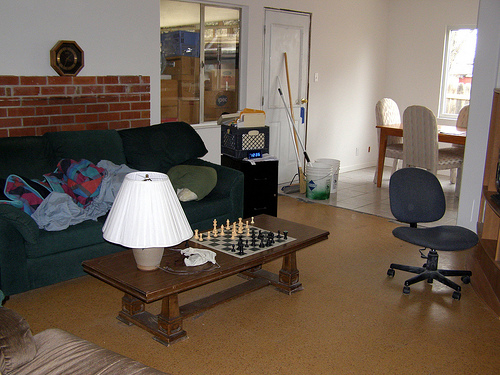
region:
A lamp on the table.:
[100, 149, 190, 272]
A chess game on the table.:
[201, 203, 297, 277]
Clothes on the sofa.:
[23, 122, 140, 212]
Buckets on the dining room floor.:
[286, 140, 353, 198]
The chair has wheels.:
[385, 253, 486, 294]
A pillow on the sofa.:
[152, 168, 230, 213]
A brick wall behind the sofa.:
[13, 63, 160, 131]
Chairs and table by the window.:
[355, 88, 467, 168]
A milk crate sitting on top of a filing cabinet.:
[220, 116, 275, 156]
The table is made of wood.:
[95, 252, 220, 337]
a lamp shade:
[97, 178, 190, 245]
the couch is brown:
[24, 338, 86, 373]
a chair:
[402, 115, 434, 163]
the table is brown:
[97, 255, 135, 289]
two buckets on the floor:
[306, 157, 339, 197]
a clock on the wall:
[47, 43, 91, 77]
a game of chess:
[202, 227, 272, 252]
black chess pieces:
[234, 228, 287, 251]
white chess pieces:
[197, 220, 259, 239]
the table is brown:
[387, 121, 399, 134]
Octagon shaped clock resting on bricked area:
[44, 31, 89, 80]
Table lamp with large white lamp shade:
[98, 167, 198, 273]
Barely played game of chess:
[188, 210, 297, 260]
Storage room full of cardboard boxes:
[160, 5, 240, 121]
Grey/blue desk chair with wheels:
[375, 159, 482, 317]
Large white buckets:
[302, 153, 342, 203]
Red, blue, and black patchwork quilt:
[2, 160, 169, 232]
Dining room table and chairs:
[363, 85, 480, 200]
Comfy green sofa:
[2, 123, 244, 289]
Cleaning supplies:
[273, 40, 327, 199]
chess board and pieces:
[185, 219, 294, 257]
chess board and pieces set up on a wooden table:
[189, 217, 295, 259]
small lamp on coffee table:
[100, 167, 195, 274]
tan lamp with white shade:
[100, 169, 195, 269]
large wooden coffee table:
[77, 209, 332, 347]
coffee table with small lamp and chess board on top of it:
[74, 210, 333, 346]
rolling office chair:
[375, 162, 474, 306]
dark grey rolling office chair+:
[373, 165, 475, 304]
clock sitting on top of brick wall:
[42, 39, 91, 76]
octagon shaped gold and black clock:
[48, 39, 83, 76]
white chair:
[402, 111, 432, 168]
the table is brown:
[122, 278, 177, 335]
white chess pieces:
[209, 223, 243, 235]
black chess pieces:
[227, 230, 284, 252]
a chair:
[392, 173, 473, 261]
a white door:
[265, 13, 307, 91]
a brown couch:
[17, 333, 86, 373]